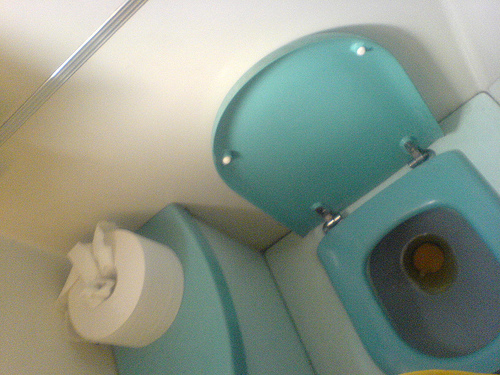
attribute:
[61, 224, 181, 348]
toilet paper — white, roll, large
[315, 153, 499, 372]
seat — blue, aqua, plastic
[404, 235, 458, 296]
water — yellowed, yellow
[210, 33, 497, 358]
toilet — blue, unflushed, soiled, dirty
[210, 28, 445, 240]
lid — aqua, blue, plastic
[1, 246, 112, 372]
wall — beige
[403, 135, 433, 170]
hinge — silver, metal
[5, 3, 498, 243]
wall — cream colored, white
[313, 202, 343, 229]
hinge — silver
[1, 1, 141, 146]
trim — metal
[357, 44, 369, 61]
lid guard — white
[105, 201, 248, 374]
tank top — blue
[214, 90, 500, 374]
base — light blue